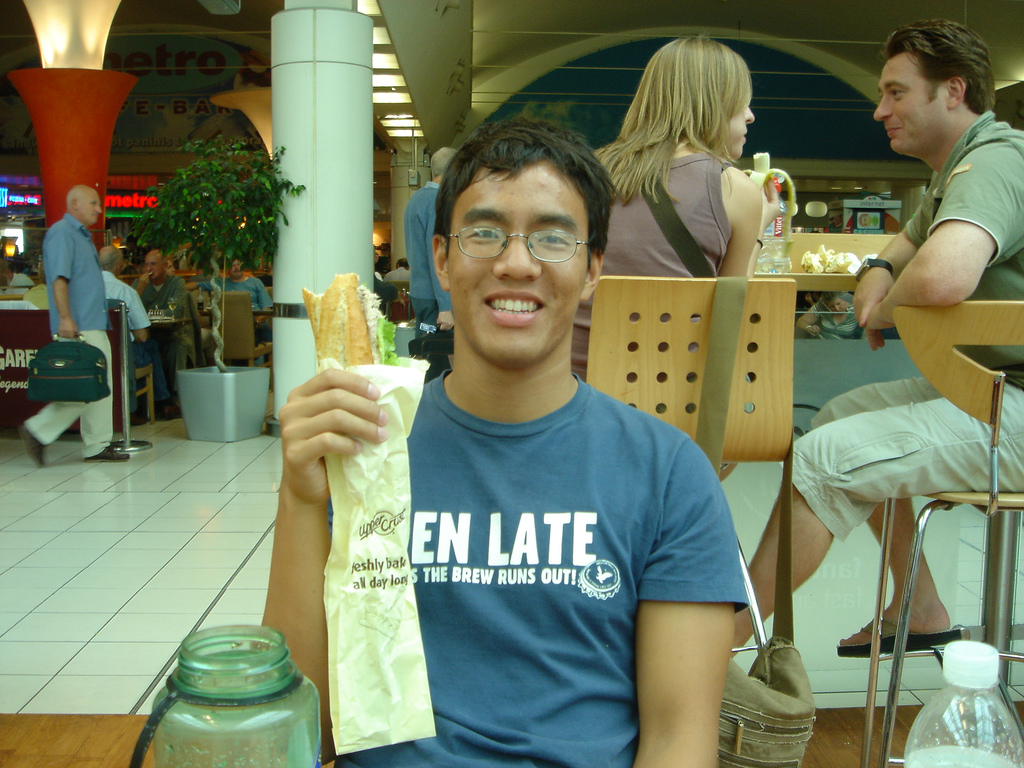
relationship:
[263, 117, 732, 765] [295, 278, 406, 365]
boy holding sandwich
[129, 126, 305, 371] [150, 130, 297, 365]
planter in a planter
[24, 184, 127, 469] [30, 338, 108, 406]
man carrying a bag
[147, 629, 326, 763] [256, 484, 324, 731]
jar beside a arm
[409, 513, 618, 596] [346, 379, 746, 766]
writing on a shirt